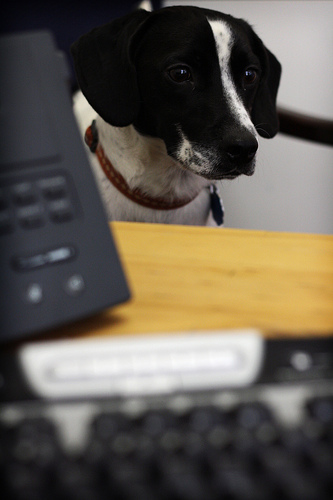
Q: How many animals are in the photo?
A: 1.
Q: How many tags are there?
A: 1.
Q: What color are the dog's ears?
A: Black.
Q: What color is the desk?
A: Tan.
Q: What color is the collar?
A: Brown.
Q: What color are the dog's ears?
A: Black.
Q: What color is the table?
A: Brown.